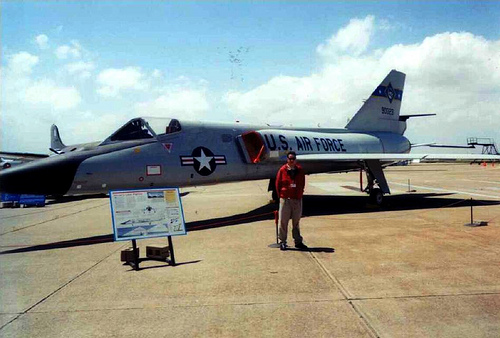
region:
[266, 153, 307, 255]
the man standing by the jet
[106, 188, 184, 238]
a sign next to the plane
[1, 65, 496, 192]
the jet plane the man is standing next to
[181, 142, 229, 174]
the air force logo on the side of the plane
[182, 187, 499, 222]
the shadow of the plane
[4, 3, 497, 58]
the blue sky above the plane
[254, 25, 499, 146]
a big white cloud in the sky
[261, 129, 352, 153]
the name of the group that owns the plane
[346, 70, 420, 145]
the tail of the plane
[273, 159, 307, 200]
the red jacket the man is wearing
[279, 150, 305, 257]
the man is standing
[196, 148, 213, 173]
the star is white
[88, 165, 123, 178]
the jet is gray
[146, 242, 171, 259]
the cinder block is holding the sign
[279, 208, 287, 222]
the pants are tan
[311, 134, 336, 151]
the word is blue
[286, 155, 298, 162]
he is wearing sunglasses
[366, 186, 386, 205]
the tire is black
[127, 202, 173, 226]
the sign is white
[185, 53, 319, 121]
clouds in the sky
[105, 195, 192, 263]
sign on the ground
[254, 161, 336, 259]
the man is standing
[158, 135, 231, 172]
army sign on airplane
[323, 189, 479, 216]
shadow of the wing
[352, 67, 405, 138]
tail of the plane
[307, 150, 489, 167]
wing of the plane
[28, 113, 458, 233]
plane and man on runway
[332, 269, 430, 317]
runway made of stone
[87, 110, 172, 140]
windshield of the plane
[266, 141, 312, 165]
face of the person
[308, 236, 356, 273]
shadow on the ground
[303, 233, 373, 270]
shadow of the person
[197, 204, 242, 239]
shadow of the plane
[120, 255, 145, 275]
stand on the floor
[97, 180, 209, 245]
a board in the port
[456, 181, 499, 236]
a small object in ground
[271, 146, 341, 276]
a man standing in ground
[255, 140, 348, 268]
a man standing next to plane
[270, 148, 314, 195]
a man wearing red shirt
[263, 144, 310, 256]
A man standing next to a plane.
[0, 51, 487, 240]
a grey plane on the ground.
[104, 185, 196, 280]
A sign posted near a plane.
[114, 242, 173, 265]
Grey cinder blocks on the ground.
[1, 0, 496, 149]
A blue sky with large white clouds.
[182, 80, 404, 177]
Decals on the side of a plane.